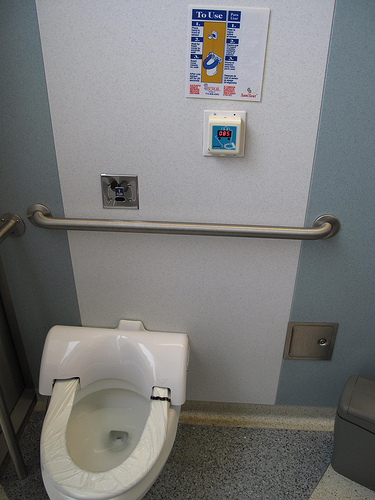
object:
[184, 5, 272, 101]
sign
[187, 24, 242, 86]
writing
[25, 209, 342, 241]
bar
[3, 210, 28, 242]
bar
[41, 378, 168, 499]
seat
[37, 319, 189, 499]
toilet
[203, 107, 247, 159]
thermostat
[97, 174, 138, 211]
flush button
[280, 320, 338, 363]
access panel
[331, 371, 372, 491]
trash bin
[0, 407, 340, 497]
flooring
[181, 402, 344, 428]
baseboard